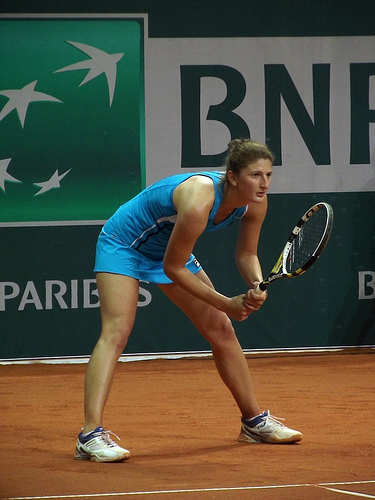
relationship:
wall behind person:
[281, 93, 365, 169] [75, 139, 270, 454]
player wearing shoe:
[74, 134, 303, 466] [237, 412, 304, 443]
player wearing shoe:
[74, 134, 303, 466] [72, 425, 131, 461]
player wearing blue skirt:
[49, 134, 303, 449] [93, 230, 201, 280]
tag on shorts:
[104, 227, 166, 251] [94, 232, 203, 283]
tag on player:
[104, 227, 166, 251] [74, 134, 303, 466]